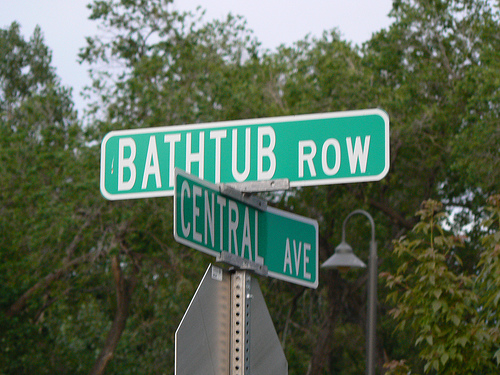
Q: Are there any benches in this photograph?
A: No, there are no benches.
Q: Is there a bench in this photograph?
A: No, there are no benches.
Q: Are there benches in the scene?
A: No, there are no benches.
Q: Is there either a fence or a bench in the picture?
A: No, there are no benches or fences.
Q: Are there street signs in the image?
A: Yes, there is a street sign.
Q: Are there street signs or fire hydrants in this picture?
A: Yes, there is a street sign.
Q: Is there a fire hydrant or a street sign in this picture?
A: Yes, there is a street sign.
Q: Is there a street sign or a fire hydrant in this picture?
A: Yes, there is a street sign.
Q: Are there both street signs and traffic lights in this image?
A: No, there is a street sign but no traffic lights.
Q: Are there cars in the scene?
A: No, there are no cars.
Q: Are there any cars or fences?
A: No, there are no cars or fences.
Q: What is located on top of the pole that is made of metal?
A: The street sign is on top of the pole.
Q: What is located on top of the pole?
A: The street sign is on top of the pole.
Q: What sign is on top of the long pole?
A: The sign is a street sign.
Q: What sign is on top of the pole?
A: The sign is a street sign.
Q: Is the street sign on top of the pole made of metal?
A: Yes, the street sign is on top of the pole.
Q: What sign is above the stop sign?
A: The sign is a street sign.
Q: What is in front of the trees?
A: The street sign is in front of the trees.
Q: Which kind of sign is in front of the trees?
A: The sign is a street sign.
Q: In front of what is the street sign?
A: The street sign is in front of the trees.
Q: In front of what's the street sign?
A: The street sign is in front of the trees.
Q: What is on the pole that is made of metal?
A: The street sign is on the pole.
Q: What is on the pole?
A: The street sign is on the pole.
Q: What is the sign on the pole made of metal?
A: The sign is a street sign.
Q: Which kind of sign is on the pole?
A: The sign is a street sign.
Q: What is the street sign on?
A: The street sign is on the pole.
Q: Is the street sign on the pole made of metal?
A: Yes, the street sign is on the pole.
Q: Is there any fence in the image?
A: No, there are no fences.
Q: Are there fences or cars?
A: No, there are no fences or cars.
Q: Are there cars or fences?
A: No, there are no fences or cars.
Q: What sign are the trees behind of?
A: The trees are behind the street sign.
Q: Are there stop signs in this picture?
A: Yes, there is a stop sign.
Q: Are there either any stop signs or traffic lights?
A: Yes, there is a stop sign.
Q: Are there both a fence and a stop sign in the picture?
A: No, there is a stop sign but no fences.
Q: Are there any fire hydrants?
A: No, there are no fire hydrants.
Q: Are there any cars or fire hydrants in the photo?
A: No, there are no fire hydrants or cars.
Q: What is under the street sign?
A: The stop sign is under the street sign.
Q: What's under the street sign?
A: The stop sign is under the street sign.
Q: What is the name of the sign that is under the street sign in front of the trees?
A: The sign is a stop sign.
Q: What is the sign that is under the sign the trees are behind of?
A: The sign is a stop sign.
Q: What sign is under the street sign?
A: The sign is a stop sign.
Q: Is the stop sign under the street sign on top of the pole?
A: Yes, the stop sign is under the street sign.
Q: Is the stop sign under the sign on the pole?
A: Yes, the stop sign is under the street sign.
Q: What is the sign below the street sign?
A: The sign is a stop sign.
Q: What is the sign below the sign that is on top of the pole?
A: The sign is a stop sign.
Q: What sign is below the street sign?
A: The sign is a stop sign.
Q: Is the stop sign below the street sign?
A: Yes, the stop sign is below the street sign.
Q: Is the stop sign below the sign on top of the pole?
A: Yes, the stop sign is below the street sign.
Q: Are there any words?
A: Yes, there are words.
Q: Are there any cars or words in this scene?
A: Yes, there are words.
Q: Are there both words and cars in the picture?
A: No, there are words but no cars.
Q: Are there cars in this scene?
A: No, there are no cars.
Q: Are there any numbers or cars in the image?
A: No, there are no cars or numbers.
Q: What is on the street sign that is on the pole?
A: The words are on the street sign.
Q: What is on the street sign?
A: The words are on the street sign.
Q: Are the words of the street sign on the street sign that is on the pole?
A: Yes, the words are on the street sign.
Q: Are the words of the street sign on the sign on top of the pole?
A: Yes, the words are on the street sign.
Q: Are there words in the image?
A: Yes, there are words.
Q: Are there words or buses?
A: Yes, there are words.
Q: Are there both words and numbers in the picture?
A: No, there are words but no numbers.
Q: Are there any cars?
A: No, there are no cars.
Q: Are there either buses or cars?
A: No, there are no cars or buses.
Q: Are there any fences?
A: No, there are no fences.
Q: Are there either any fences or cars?
A: No, there are no fences or cars.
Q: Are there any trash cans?
A: No, there are no trash cans.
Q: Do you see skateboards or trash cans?
A: No, there are no trash cans or skateboards.